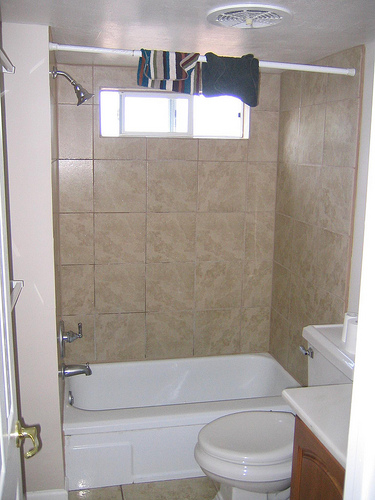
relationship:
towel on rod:
[125, 43, 263, 116] [61, 37, 360, 87]